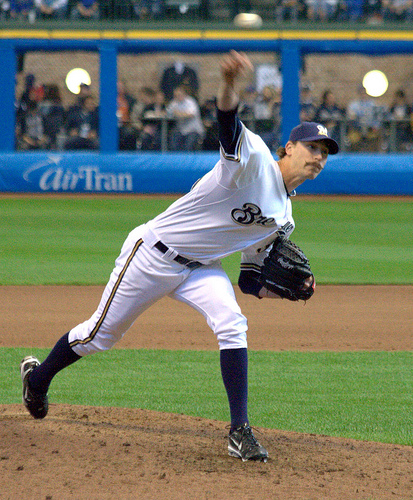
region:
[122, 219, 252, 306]
player is wearing a belt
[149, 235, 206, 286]
player is wearing a belt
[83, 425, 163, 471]
dirt on the ground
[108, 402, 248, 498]
dirt on the ground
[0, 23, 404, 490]
Photo taken at a baseball game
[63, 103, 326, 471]
Man pitching a baseball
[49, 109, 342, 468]
The pitcher is right handed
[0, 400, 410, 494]
Pitcher's mound made of dirt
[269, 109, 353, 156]
Hat on the man's head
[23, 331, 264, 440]
Blue socks on the player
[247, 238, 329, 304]
Black glove on the left hand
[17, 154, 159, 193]
AirTran ad on the far wall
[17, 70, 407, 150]
Spectators watching the game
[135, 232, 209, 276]
Belt on the uniform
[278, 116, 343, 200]
player has a mustache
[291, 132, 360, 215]
player has a mustache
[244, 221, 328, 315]
the glove is black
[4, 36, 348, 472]
man pitching the ball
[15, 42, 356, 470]
baseball player on the mound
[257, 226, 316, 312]
man's black baseball glove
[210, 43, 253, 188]
right arm throwing the ball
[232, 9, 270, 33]
ball in the air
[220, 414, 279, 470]
left foot planted in the dirt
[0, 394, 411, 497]
dirt covering the pitcher's mound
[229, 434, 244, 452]
nike swoosh on the shoe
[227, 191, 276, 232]
writing on the front of the shirt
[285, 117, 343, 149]
man's blue baseball cap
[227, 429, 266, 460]
A black shoe on the left foot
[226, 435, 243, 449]
A Nike logo on the shoe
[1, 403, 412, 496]
The pitcher's mound below the pitcher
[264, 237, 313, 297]
A black glove on the left hand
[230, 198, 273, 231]
The team logo on the shirt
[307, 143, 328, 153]
The eyes of the man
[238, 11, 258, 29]
A baseball in the air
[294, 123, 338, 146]
The man is wearing a hat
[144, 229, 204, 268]
The man is wearing a belt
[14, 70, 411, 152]
An audience watching the game